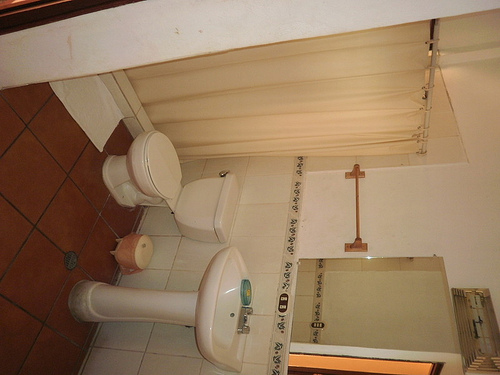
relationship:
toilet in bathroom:
[109, 127, 237, 242] [4, 5, 499, 374]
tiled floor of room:
[8, 80, 149, 372] [2, 0, 494, 373]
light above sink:
[394, 33, 473, 128] [192, 250, 265, 373]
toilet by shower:
[109, 127, 237, 242] [99, 15, 430, 183]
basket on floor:
[111, 229, 153, 276] [1, 42, 151, 374]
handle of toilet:
[217, 168, 230, 178] [109, 127, 237, 242]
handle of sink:
[235, 324, 255, 336] [192, 242, 252, 367]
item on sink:
[241, 275, 254, 303] [62, 243, 260, 370]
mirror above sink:
[289, 254, 466, 351] [173, 208, 297, 368]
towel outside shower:
[36, 70, 128, 157] [129, 40, 450, 162]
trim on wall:
[266, 153, 306, 373] [123, 135, 447, 373]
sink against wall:
[62, 243, 260, 370] [75, 56, 497, 372]